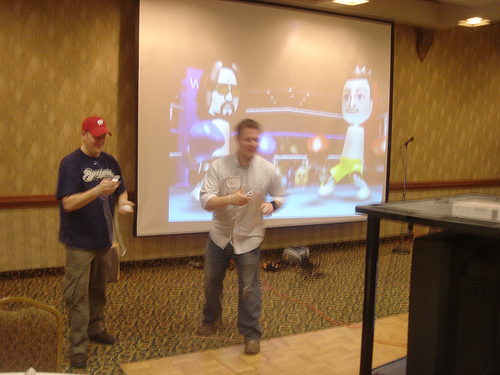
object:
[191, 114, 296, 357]
man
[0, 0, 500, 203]
wallpaper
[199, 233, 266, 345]
jeans.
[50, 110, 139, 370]
man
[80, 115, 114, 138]
hat.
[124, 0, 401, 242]
screen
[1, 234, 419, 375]
floor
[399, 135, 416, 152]
microphone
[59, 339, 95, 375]
shoes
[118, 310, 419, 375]
mat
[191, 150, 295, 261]
shirt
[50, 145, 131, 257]
tshirt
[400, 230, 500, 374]
tv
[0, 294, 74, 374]
chair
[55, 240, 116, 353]
pants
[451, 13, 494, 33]
light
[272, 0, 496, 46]
ceiling.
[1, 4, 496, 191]
wall.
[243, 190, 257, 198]
controller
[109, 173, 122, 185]
remote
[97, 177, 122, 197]
hand.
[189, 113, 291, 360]
guys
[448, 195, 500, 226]
wii.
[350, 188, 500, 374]
stand.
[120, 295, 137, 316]
pattern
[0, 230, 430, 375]
carpet.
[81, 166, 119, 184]
writing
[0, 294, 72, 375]
frame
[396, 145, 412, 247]
stand.